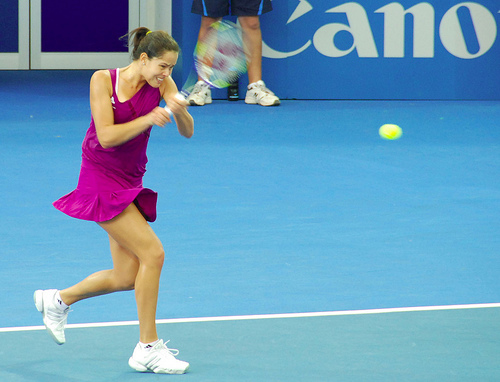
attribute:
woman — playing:
[29, 21, 205, 381]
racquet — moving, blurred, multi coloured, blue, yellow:
[184, 21, 263, 105]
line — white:
[5, 286, 499, 341]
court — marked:
[8, 104, 499, 381]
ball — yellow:
[378, 119, 404, 143]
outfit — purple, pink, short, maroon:
[48, 66, 174, 218]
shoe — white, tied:
[133, 338, 192, 376]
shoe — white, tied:
[31, 287, 72, 348]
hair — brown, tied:
[127, 26, 177, 59]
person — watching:
[186, 4, 281, 113]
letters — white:
[314, 3, 497, 68]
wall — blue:
[149, 2, 493, 105]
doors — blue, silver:
[4, 2, 146, 77]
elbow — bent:
[88, 131, 119, 151]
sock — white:
[139, 340, 164, 349]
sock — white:
[52, 289, 68, 311]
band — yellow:
[142, 30, 152, 36]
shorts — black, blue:
[191, 0, 276, 19]